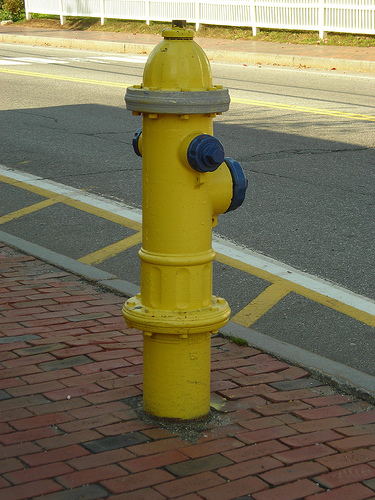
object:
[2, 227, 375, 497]
sidewalk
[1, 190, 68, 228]
lines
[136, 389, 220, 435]
base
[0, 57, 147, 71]
lines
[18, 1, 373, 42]
fence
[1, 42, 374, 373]
street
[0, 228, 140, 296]
curb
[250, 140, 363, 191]
cracks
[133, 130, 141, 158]
bolts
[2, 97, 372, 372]
shadow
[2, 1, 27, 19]
bush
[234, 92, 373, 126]
line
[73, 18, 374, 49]
grass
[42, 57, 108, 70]
marks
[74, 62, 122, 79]
brink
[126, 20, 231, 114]
top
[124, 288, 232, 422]
bottom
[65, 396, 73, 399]
spot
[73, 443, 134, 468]
brick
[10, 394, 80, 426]
bricks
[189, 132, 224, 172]
blue nozzle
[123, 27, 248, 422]
fire hydrant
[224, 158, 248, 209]
blue nozzle